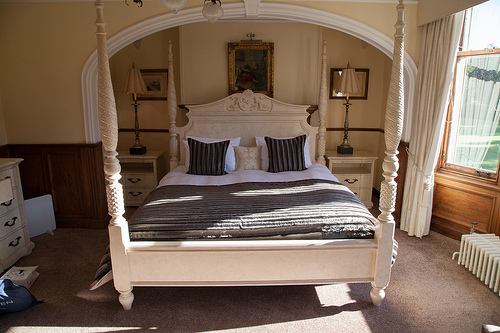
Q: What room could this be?
A: It is a bedroom.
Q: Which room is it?
A: It is a bedroom.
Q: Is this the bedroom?
A: Yes, it is the bedroom.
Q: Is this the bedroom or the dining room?
A: It is the bedroom.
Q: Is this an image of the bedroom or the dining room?
A: It is showing the bedroom.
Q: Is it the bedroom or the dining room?
A: It is the bedroom.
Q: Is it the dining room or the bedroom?
A: It is the bedroom.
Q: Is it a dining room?
A: No, it is a bedroom.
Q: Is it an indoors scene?
A: Yes, it is indoors.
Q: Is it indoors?
A: Yes, it is indoors.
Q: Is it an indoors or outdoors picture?
A: It is indoors.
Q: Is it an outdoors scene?
A: No, it is indoors.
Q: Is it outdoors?
A: No, it is indoors.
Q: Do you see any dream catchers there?
A: No, there are no dream catchers.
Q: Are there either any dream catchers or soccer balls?
A: No, there are no dream catchers or soccer balls.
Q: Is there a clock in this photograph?
A: No, there are no clocks.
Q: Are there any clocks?
A: No, there are no clocks.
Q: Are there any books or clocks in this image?
A: No, there are no clocks or books.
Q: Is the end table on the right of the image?
A: Yes, the end table is on the right of the image.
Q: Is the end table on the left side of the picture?
A: No, the end table is on the right of the image.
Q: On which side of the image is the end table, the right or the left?
A: The end table is on the right of the image.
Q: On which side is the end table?
A: The end table is on the right of the image.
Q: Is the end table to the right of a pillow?
A: Yes, the end table is to the right of a pillow.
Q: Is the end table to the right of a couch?
A: No, the end table is to the right of a pillow.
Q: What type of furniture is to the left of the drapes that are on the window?
A: The piece of furniture is an end table.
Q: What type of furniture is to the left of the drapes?
A: The piece of furniture is an end table.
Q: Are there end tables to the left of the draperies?
A: Yes, there is an end table to the left of the draperies.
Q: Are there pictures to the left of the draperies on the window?
A: No, there is an end table to the left of the drapes.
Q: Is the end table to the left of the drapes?
A: Yes, the end table is to the left of the drapes.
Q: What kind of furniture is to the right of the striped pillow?
A: The piece of furniture is an end table.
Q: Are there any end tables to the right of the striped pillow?
A: Yes, there is an end table to the right of the pillow.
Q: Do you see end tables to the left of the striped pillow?
A: No, the end table is to the right of the pillow.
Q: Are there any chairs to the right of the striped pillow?
A: No, there is an end table to the right of the pillow.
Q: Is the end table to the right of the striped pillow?
A: Yes, the end table is to the right of the pillow.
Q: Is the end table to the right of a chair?
A: No, the end table is to the right of the pillow.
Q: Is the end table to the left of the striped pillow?
A: No, the end table is to the right of the pillow.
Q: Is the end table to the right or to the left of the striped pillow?
A: The end table is to the right of the pillow.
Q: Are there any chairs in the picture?
A: No, there are no chairs.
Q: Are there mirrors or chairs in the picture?
A: No, there are no chairs or mirrors.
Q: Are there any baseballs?
A: No, there are no baseballs.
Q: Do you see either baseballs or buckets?
A: No, there are no baseballs or buckets.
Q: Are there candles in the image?
A: No, there are no candles.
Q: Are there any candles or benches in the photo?
A: No, there are no candles or benches.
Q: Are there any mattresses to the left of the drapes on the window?
A: Yes, there is a mattress to the left of the draperies.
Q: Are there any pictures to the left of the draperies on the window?
A: No, there is a mattress to the left of the drapes.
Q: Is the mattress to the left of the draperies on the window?
A: Yes, the mattress is to the left of the draperies.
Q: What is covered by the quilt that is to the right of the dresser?
A: The mattress is covered by the comforter.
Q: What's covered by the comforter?
A: The mattress is covered by the comforter.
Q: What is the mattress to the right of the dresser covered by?
A: The mattress is covered by the quilt.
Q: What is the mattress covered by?
A: The mattress is covered by the quilt.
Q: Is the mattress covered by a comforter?
A: Yes, the mattress is covered by a comforter.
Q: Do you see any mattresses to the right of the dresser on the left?
A: Yes, there is a mattress to the right of the dresser.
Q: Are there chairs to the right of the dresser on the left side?
A: No, there is a mattress to the right of the dresser.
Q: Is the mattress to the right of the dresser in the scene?
A: Yes, the mattress is to the right of the dresser.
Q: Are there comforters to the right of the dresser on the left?
A: Yes, there is a comforter to the right of the dresser.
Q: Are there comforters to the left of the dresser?
A: No, the comforter is to the right of the dresser.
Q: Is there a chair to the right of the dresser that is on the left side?
A: No, there is a comforter to the right of the dresser.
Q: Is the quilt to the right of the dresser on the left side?
A: Yes, the quilt is to the right of the dresser.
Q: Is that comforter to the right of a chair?
A: No, the comforter is to the right of the dresser.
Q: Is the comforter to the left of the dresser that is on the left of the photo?
A: No, the comforter is to the right of the dresser.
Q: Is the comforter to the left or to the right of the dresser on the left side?
A: The comforter is to the right of the dresser.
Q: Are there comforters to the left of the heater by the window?
A: Yes, there is a comforter to the left of the heater.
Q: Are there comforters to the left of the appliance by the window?
A: Yes, there is a comforter to the left of the heater.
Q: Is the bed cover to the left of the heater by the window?
A: Yes, the bed cover is to the left of the heater.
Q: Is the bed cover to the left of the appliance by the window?
A: Yes, the bed cover is to the left of the heater.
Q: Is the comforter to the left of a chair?
A: No, the comforter is to the left of the heater.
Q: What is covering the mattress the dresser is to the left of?
A: The quilt is covering the mattress.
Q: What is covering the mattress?
A: The quilt is covering the mattress.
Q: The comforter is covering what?
A: The comforter is covering the mattress.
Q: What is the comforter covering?
A: The comforter is covering the mattress.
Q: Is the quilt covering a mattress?
A: Yes, the quilt is covering a mattress.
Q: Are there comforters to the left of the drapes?
A: Yes, there is a comforter to the left of the drapes.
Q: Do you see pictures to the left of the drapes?
A: No, there is a comforter to the left of the drapes.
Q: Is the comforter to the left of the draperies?
A: Yes, the comforter is to the left of the draperies.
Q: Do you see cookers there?
A: No, there are no cookers.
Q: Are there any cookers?
A: No, there are no cookers.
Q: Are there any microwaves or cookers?
A: No, there are no cookers or microwaves.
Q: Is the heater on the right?
A: Yes, the heater is on the right of the image.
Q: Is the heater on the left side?
A: No, the heater is on the right of the image.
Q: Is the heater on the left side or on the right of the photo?
A: The heater is on the right of the image.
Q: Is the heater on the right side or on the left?
A: The heater is on the right of the image.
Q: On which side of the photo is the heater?
A: The heater is on the right of the image.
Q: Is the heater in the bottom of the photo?
A: Yes, the heater is in the bottom of the image.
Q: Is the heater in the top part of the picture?
A: No, the heater is in the bottom of the image.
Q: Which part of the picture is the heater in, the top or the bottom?
A: The heater is in the bottom of the image.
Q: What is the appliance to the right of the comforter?
A: The appliance is a heater.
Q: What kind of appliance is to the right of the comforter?
A: The appliance is a heater.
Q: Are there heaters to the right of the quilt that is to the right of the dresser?
A: Yes, there is a heater to the right of the comforter.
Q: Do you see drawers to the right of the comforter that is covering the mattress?
A: No, there is a heater to the right of the comforter.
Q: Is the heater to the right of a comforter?
A: Yes, the heater is to the right of a comforter.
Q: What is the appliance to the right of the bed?
A: The appliance is a heater.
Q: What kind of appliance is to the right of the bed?
A: The appliance is a heater.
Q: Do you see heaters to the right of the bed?
A: Yes, there is a heater to the right of the bed.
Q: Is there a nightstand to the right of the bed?
A: No, there is a heater to the right of the bed.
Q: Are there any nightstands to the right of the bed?
A: No, there is a heater to the right of the bed.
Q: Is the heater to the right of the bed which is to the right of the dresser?
A: Yes, the heater is to the right of the bed.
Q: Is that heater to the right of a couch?
A: No, the heater is to the right of the bed.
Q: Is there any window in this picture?
A: Yes, there is a window.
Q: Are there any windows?
A: Yes, there is a window.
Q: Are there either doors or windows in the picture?
A: Yes, there is a window.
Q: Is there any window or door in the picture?
A: Yes, there is a window.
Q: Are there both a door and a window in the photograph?
A: No, there is a window but no doors.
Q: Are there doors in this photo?
A: No, there are no doors.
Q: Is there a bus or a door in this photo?
A: No, there are no doors or buses.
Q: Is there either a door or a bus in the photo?
A: No, there are no doors or buses.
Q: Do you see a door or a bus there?
A: No, there are no doors or buses.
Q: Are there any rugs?
A: No, there are no rugs.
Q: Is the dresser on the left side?
A: Yes, the dresser is on the left of the image.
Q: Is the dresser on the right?
A: No, the dresser is on the left of the image.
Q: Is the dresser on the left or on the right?
A: The dresser is on the left of the image.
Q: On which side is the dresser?
A: The dresser is on the left of the image.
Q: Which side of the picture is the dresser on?
A: The dresser is on the left of the image.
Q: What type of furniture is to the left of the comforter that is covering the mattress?
A: The piece of furniture is a dresser.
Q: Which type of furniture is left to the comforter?
A: The piece of furniture is a dresser.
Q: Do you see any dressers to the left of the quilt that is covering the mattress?
A: Yes, there is a dresser to the left of the bed cover.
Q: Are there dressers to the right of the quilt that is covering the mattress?
A: No, the dresser is to the left of the comforter.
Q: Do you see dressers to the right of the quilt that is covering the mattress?
A: No, the dresser is to the left of the comforter.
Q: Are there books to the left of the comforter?
A: No, there is a dresser to the left of the comforter.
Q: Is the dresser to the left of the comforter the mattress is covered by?
A: Yes, the dresser is to the left of the comforter.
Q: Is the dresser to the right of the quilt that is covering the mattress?
A: No, the dresser is to the left of the comforter.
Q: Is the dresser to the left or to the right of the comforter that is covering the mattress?
A: The dresser is to the left of the comforter.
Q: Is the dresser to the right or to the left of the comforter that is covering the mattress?
A: The dresser is to the left of the comforter.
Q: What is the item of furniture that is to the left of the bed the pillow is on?
A: The piece of furniture is a dresser.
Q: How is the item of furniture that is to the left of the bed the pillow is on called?
A: The piece of furniture is a dresser.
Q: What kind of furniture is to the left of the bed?
A: The piece of furniture is a dresser.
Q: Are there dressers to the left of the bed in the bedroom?
A: Yes, there is a dresser to the left of the bed.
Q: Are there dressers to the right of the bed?
A: No, the dresser is to the left of the bed.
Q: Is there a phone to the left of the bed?
A: No, there is a dresser to the left of the bed.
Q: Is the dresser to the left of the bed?
A: Yes, the dresser is to the left of the bed.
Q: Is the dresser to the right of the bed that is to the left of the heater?
A: No, the dresser is to the left of the bed.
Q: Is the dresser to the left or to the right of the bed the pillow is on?
A: The dresser is to the left of the bed.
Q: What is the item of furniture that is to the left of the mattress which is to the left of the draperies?
A: The piece of furniture is a dresser.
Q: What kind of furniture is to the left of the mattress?
A: The piece of furniture is a dresser.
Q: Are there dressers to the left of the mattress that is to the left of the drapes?
A: Yes, there is a dresser to the left of the mattress.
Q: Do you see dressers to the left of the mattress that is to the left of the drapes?
A: Yes, there is a dresser to the left of the mattress.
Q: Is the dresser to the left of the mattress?
A: Yes, the dresser is to the left of the mattress.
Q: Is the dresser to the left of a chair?
A: No, the dresser is to the left of the mattress.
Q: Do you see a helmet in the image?
A: No, there are no helmets.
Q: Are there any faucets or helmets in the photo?
A: No, there are no helmets or faucets.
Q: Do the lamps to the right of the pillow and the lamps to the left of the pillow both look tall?
A: Yes, both the lamps and the lamps are tall.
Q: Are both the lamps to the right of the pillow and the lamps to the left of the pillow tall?
A: Yes, both the lamps and the lamps are tall.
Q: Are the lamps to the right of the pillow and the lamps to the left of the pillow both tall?
A: Yes, both the lamps and the lamps are tall.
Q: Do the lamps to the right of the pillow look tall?
A: Yes, the lamps are tall.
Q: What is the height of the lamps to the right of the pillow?
A: The lamps are tall.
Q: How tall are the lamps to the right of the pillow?
A: The lamps are tall.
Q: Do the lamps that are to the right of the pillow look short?
A: No, the lamps are tall.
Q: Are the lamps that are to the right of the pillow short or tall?
A: The lamps are tall.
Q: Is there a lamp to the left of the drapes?
A: Yes, there are lamps to the left of the drapes.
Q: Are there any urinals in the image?
A: No, there are no urinals.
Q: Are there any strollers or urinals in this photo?
A: No, there are no urinals or strollers.